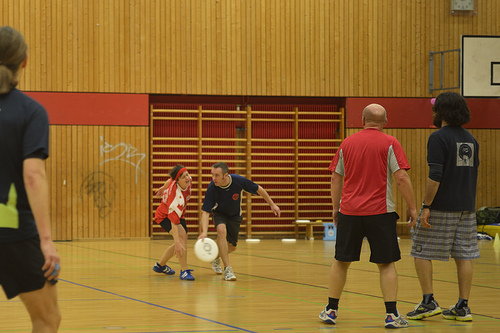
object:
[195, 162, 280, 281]
man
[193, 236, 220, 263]
frisbee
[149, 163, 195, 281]
woman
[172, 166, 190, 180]
headband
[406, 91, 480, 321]
man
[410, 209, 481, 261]
shorts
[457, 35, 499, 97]
basketball goal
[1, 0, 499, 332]
gym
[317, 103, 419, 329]
man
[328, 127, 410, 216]
shirt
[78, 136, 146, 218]
graffiti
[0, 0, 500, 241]
wall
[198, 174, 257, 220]
shirt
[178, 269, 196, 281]
sneakers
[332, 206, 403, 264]
shorts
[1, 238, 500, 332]
floor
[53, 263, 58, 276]
wrap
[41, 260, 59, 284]
finger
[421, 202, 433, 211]
wristwatch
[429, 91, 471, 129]
hair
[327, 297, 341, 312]
socks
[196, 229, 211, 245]
right hand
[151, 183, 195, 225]
shirt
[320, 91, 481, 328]
men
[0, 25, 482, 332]
people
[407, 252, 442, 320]
left leg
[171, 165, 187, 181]
hair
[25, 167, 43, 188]
elbow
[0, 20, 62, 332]
person